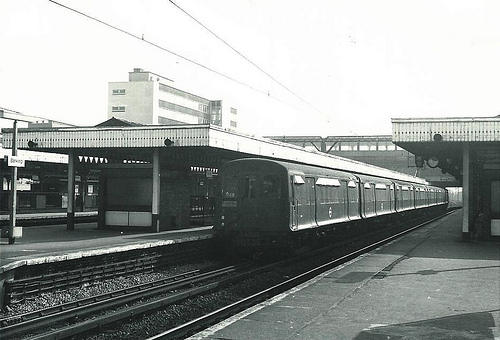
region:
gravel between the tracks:
[82, 273, 133, 299]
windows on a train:
[319, 179, 346, 206]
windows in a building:
[159, 80, 196, 119]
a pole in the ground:
[63, 186, 84, 234]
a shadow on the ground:
[395, 257, 447, 282]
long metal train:
[211, 153, 451, 255]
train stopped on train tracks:
[2, 154, 453, 338]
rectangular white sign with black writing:
[5, 152, 26, 168]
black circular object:
[160, 135, 175, 148]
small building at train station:
[91, 157, 187, 232]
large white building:
[100, 65, 237, 132]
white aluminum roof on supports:
[2, 123, 428, 234]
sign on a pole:
[5, 117, 30, 243]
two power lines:
[46, 0, 308, 101]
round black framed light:
[422, 149, 441, 170]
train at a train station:
[214, 156, 447, 240]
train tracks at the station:
[4, 235, 389, 339]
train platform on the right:
[205, 206, 497, 338]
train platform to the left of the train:
[0, 215, 215, 270]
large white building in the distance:
[107, 69, 239, 128]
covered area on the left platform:
[7, 130, 429, 225]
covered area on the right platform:
[392, 117, 497, 244]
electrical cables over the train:
[48, 0, 304, 100]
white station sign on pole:
[7, 155, 26, 165]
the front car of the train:
[215, 157, 360, 257]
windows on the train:
[282, 167, 447, 211]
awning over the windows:
[295, 175, 379, 190]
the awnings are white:
[295, 176, 362, 193]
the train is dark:
[232, 160, 409, 235]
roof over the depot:
[17, 124, 280, 156]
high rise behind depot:
[101, 69, 275, 156]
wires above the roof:
[111, 3, 326, 161]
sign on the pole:
[9, 116, 24, 243]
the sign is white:
[9, 152, 26, 169]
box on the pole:
[7, 217, 34, 247]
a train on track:
[204, 149, 462, 273]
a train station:
[0, 97, 498, 338]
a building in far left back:
[105, 59, 250, 122]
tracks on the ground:
[0, 227, 277, 339]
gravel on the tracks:
[5, 245, 260, 337]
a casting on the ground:
[329, 257, 499, 339]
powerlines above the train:
[34, 0, 348, 120]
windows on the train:
[290, 177, 451, 212]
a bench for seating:
[93, 194, 173, 232]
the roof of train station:
[0, 114, 495, 143]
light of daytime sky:
[0, 2, 499, 131]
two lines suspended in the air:
[51, 1, 308, 101]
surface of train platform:
[200, 202, 497, 338]